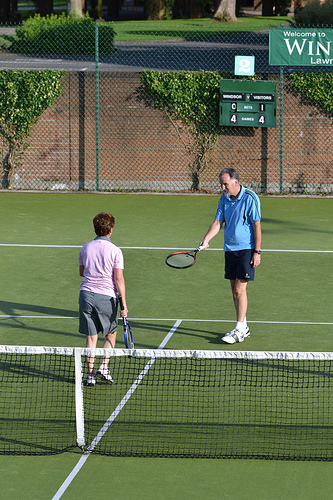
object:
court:
[0, 188, 332, 498]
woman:
[77, 212, 129, 390]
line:
[49, 319, 185, 500]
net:
[0, 345, 332, 457]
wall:
[0, 69, 333, 195]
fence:
[0, 20, 333, 197]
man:
[198, 168, 262, 345]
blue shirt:
[214, 184, 263, 250]